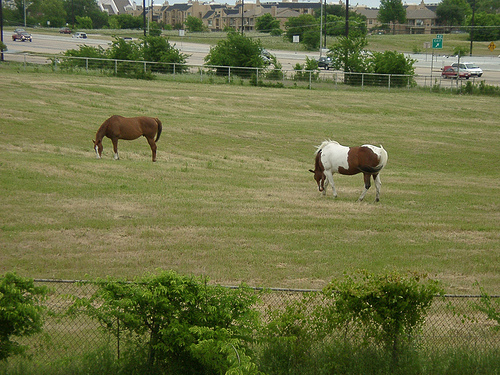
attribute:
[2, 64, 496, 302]
grass — short, green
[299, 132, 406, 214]
horse — brown, white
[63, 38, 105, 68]
tree — tall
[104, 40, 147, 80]
tree — tall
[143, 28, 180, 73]
tree — tall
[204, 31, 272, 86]
tree — tall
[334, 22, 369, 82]
tree — tall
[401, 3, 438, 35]
building — row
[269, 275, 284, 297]
fence — edge 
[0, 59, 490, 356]
grass — short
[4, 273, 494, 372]
fence — chain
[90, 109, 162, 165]
horse — brown, white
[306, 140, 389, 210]
horse — white, brown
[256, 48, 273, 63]
car — red